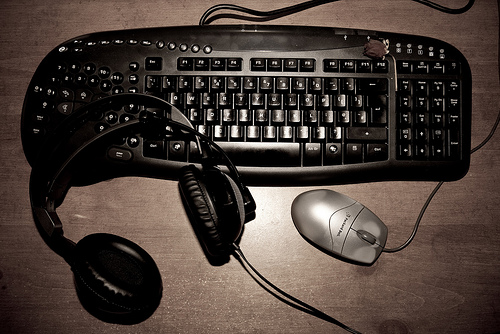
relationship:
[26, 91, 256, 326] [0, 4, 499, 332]
headphones on table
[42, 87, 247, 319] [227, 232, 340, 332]
headphones have cord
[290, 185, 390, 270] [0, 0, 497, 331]
grey mouse on desk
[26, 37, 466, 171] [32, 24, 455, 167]
keys on keyboard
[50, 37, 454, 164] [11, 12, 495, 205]
keys on keyboard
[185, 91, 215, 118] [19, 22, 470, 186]
keys on keyboard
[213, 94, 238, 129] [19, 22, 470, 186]
keys on keyboard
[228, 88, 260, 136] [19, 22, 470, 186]
keys on keyboard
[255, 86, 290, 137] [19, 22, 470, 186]
keys on keyboard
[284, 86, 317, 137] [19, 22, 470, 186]
keys on keyboard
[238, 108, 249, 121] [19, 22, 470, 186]
key on keyboard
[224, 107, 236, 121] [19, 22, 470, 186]
key on keyboard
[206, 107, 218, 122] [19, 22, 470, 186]
key on keyboard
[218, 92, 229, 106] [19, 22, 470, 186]
key on keyboard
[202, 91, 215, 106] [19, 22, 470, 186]
key on keyboard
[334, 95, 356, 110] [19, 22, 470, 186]
keys on keyboard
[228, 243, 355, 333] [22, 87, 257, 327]
cord on headphone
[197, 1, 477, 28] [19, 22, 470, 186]
black cord on keyboard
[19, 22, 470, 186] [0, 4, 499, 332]
keyboard on table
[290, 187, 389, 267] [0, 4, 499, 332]
grey mouse on table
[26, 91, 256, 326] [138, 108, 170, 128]
headphones with microphone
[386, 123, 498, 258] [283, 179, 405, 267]
cord coming from mouse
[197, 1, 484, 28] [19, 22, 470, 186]
black cord coming from keyboard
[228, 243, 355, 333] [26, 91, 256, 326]
cord coming from headphones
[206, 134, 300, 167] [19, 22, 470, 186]
spacebar on keyboard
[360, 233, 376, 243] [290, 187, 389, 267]
wheel on grey mouse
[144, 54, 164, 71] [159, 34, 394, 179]
escape key on keyboard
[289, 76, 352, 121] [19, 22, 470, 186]
keys on keyboard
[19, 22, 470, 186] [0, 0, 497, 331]
keyboard on desk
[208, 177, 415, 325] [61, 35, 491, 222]
cord on keyboard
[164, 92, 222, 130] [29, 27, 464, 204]
keys on keyboard